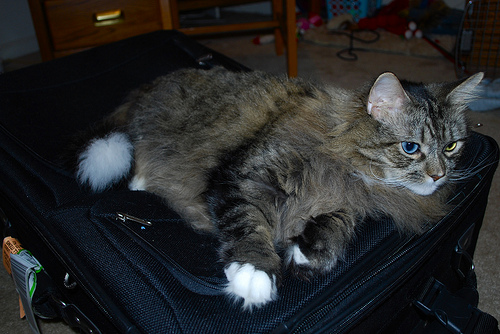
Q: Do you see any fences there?
A: No, there are no fences.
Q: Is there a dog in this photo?
A: No, there are no dogs.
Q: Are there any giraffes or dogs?
A: No, there are no dogs or giraffes.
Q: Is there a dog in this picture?
A: No, there are no dogs.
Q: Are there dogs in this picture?
A: No, there are no dogs.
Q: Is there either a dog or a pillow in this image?
A: No, there are no dogs or pillows.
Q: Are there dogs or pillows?
A: No, there are no dogs or pillows.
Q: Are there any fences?
A: No, there are no fences.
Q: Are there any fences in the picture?
A: No, there are no fences.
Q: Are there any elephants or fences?
A: No, there are no fences or elephants.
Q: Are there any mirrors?
A: No, there are no mirrors.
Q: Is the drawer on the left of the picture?
A: Yes, the drawer is on the left of the image.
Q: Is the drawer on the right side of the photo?
A: No, the drawer is on the left of the image.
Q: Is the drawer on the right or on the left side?
A: The drawer is on the left of the image.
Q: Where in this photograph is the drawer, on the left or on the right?
A: The drawer is on the left of the image.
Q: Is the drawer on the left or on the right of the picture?
A: The drawer is on the left of the image.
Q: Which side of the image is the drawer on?
A: The drawer is on the left of the image.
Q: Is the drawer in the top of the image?
A: Yes, the drawer is in the top of the image.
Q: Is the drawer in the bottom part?
A: No, the drawer is in the top of the image.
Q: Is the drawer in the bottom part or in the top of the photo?
A: The drawer is in the top of the image.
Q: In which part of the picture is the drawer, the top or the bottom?
A: The drawer is in the top of the image.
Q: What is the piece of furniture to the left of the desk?
A: The piece of furniture is a drawer.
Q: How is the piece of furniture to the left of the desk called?
A: The piece of furniture is a drawer.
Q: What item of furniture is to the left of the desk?
A: The piece of furniture is a drawer.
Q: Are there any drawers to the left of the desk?
A: Yes, there is a drawer to the left of the desk.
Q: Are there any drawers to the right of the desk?
A: No, the drawer is to the left of the desk.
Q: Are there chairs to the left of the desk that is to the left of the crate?
A: No, there is a drawer to the left of the desk.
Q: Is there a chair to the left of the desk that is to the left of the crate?
A: No, there is a drawer to the left of the desk.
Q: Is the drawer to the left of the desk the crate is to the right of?
A: Yes, the drawer is to the left of the desk.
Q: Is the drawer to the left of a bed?
A: No, the drawer is to the left of the desk.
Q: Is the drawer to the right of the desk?
A: No, the drawer is to the left of the desk.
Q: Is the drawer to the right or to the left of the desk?
A: The drawer is to the left of the desk.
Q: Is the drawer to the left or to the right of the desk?
A: The drawer is to the left of the desk.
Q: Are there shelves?
A: No, there are no shelves.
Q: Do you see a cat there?
A: Yes, there is a cat.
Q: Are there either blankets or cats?
A: Yes, there is a cat.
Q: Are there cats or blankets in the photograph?
A: Yes, there is a cat.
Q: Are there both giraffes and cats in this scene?
A: No, there is a cat but no giraffes.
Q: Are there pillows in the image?
A: No, there are no pillows.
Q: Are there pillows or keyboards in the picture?
A: No, there are no pillows or keyboards.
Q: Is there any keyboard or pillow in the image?
A: No, there are no pillows or keyboards.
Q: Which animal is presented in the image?
A: The animal is a cat.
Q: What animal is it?
A: The animal is a cat.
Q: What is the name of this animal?
A: This is a cat.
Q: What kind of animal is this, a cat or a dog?
A: This is a cat.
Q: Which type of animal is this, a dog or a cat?
A: This is a cat.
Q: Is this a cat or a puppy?
A: This is a cat.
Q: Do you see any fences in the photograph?
A: No, there are no fences.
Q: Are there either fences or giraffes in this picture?
A: No, there are no fences or giraffes.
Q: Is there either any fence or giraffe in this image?
A: No, there are no fences or giraffes.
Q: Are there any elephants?
A: No, there are no elephants.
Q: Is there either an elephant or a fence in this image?
A: No, there are no elephants or fences.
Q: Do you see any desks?
A: Yes, there is a desk.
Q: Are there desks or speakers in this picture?
A: Yes, there is a desk.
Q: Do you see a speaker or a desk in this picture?
A: Yes, there is a desk.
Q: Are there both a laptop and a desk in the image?
A: No, there is a desk but no laptops.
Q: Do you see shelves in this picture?
A: No, there are no shelves.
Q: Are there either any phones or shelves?
A: No, there are no shelves or phones.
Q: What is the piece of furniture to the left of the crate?
A: The piece of furniture is a desk.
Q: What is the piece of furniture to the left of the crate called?
A: The piece of furniture is a desk.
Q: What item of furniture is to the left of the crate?
A: The piece of furniture is a desk.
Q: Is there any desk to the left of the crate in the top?
A: Yes, there is a desk to the left of the crate.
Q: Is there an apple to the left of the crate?
A: No, there is a desk to the left of the crate.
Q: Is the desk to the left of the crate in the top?
A: Yes, the desk is to the left of the crate.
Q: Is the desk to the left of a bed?
A: No, the desk is to the left of the crate.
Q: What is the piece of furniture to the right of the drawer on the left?
A: The piece of furniture is a desk.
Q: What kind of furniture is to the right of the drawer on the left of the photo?
A: The piece of furniture is a desk.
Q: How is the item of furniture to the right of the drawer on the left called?
A: The piece of furniture is a desk.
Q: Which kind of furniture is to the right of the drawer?
A: The piece of furniture is a desk.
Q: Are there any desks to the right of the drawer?
A: Yes, there is a desk to the right of the drawer.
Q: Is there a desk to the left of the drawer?
A: No, the desk is to the right of the drawer.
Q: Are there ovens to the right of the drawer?
A: No, there is a desk to the right of the drawer.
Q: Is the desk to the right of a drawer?
A: Yes, the desk is to the right of a drawer.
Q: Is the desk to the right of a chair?
A: No, the desk is to the right of a drawer.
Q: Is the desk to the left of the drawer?
A: No, the desk is to the right of the drawer.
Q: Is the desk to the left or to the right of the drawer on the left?
A: The desk is to the right of the drawer.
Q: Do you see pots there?
A: No, there are no pots.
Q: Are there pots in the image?
A: No, there are no pots.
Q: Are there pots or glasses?
A: No, there are no pots or glasses.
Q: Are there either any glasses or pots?
A: No, there are no pots or glasses.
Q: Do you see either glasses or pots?
A: No, there are no pots or glasses.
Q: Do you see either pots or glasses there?
A: No, there are no pots or glasses.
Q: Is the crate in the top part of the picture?
A: Yes, the crate is in the top of the image.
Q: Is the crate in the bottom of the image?
A: No, the crate is in the top of the image.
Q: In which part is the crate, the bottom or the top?
A: The crate is in the top of the image.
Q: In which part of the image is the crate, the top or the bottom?
A: The crate is in the top of the image.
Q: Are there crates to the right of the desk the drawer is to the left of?
A: Yes, there is a crate to the right of the desk.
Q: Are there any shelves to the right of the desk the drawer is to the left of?
A: No, there is a crate to the right of the desk.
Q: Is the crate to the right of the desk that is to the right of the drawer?
A: Yes, the crate is to the right of the desk.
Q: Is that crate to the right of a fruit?
A: No, the crate is to the right of the desk.